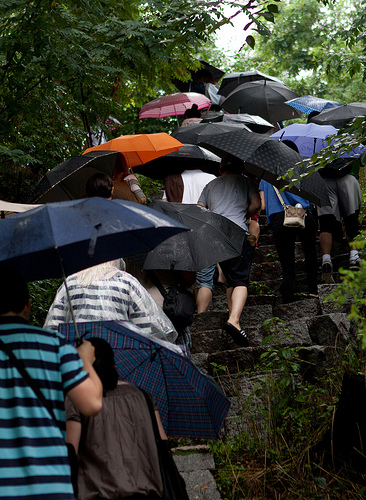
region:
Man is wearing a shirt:
[1, 308, 91, 498]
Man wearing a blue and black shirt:
[0, 317, 94, 498]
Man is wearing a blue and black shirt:
[0, 311, 92, 497]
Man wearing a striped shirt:
[0, 312, 91, 494]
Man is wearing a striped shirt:
[0, 310, 94, 493]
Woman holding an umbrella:
[54, 309, 235, 442]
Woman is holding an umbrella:
[53, 311, 231, 444]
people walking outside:
[44, 44, 308, 465]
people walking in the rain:
[66, 203, 270, 492]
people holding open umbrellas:
[40, 186, 223, 395]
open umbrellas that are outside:
[60, 186, 287, 492]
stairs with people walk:
[74, 167, 286, 496]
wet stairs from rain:
[34, 216, 334, 446]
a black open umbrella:
[131, 185, 250, 271]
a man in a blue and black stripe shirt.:
[0, 257, 116, 499]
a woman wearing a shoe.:
[221, 275, 267, 348]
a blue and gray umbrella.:
[52, 313, 230, 448]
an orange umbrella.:
[81, 124, 191, 174]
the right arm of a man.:
[68, 335, 102, 420]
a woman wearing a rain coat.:
[37, 246, 182, 342]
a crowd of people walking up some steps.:
[0, 60, 362, 495]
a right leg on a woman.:
[217, 276, 259, 354]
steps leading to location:
[166, 181, 350, 451]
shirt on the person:
[4, 321, 86, 490]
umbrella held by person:
[5, 199, 192, 332]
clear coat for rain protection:
[53, 263, 183, 346]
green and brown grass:
[212, 430, 340, 491]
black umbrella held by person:
[202, 126, 339, 203]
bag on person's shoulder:
[153, 283, 205, 326]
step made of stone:
[219, 343, 342, 369]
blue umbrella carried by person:
[277, 92, 364, 119]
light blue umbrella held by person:
[275, 120, 363, 153]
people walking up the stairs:
[92, 38, 303, 281]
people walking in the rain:
[68, 131, 252, 429]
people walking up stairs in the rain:
[99, 196, 296, 496]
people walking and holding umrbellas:
[90, 133, 211, 425]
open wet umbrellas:
[39, 193, 269, 494]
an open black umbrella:
[117, 182, 347, 338]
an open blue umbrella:
[7, 180, 139, 285]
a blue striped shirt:
[16, 300, 109, 498]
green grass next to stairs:
[188, 319, 362, 441]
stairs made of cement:
[141, 253, 304, 494]